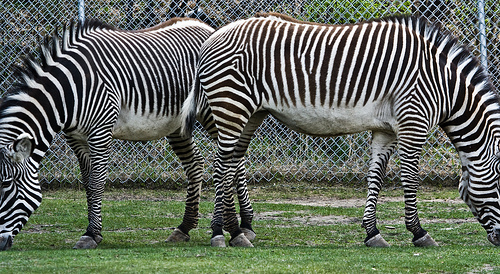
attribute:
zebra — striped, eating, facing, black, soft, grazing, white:
[194, 8, 500, 251]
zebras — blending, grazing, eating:
[1, 21, 500, 271]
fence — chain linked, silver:
[2, 1, 499, 189]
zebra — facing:
[1, 17, 235, 248]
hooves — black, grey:
[72, 231, 198, 248]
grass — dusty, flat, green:
[1, 186, 499, 271]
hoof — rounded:
[161, 227, 192, 247]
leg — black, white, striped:
[393, 115, 441, 252]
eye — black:
[2, 174, 15, 189]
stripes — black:
[194, 23, 446, 129]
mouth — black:
[1, 232, 16, 255]